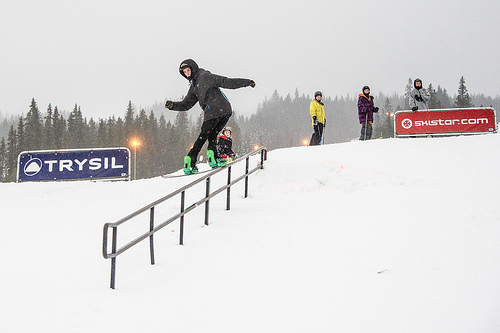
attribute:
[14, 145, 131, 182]
sign — blue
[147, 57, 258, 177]
woman — purple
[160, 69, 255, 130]
jacket — grey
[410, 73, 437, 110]
jacket — gray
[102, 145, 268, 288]
railing — metal, black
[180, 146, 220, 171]
shoes — light green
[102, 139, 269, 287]
rail — metal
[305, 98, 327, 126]
jacket — yellow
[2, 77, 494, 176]
area — large, forested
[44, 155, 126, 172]
writing — white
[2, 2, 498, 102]
sky — gray, large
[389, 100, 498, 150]
sign — red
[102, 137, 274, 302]
banisters — gray, metal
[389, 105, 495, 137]
signboard — red, white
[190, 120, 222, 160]
pants — black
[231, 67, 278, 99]
gloves — black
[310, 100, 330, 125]
jacket — yellow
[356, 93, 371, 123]
jacket — orange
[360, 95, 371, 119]
jacket — purple